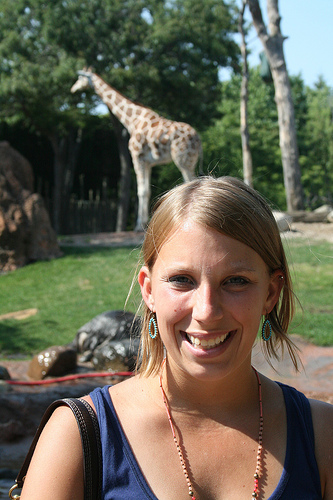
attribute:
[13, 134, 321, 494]
woman — smiling, blond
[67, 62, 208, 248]
giraffe — standing, tall, blurry, statue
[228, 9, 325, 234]
trees — green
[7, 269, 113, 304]
grass — green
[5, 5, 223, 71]
leaves — green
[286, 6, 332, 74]
sky — blue, distant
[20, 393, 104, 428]
strap — brown, leather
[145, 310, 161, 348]
earrings — blue, green, dangling, silver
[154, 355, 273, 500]
necklace — beaded, pink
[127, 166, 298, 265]
hair — blonde, parted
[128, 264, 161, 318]
ear — pierced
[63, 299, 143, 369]
stone — large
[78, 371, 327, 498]
tanktop — blue, dark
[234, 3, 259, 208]
tree — tall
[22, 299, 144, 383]
rocks — wet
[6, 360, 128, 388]
hose — red